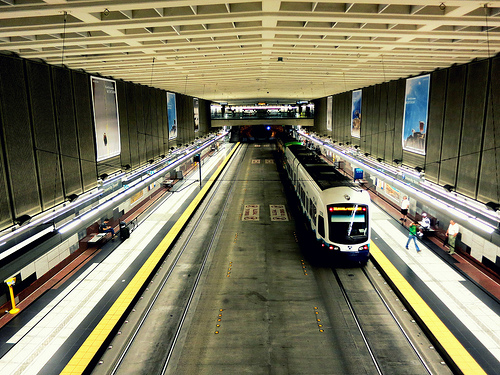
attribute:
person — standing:
[441, 216, 462, 256]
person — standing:
[392, 217, 431, 252]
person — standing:
[403, 202, 425, 257]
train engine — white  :
[309, 182, 374, 270]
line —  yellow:
[385, 250, 487, 352]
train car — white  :
[259, 132, 381, 292]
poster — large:
[91, 72, 124, 163]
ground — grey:
[225, 222, 310, 374]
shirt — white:
[418, 215, 435, 227]